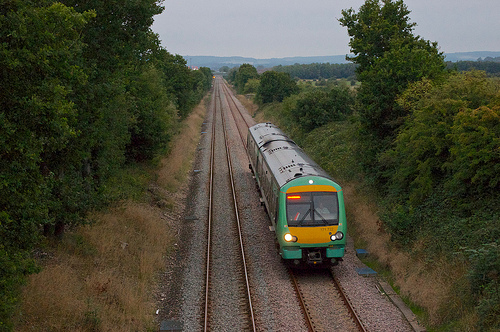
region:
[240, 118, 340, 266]
the train is in motion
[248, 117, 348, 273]
the train is green and yellow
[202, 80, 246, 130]
two rail road tracks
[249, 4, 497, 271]
the bushes are near a train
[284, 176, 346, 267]
the front of a train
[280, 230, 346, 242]
the headlights of a train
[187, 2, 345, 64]
the sky is foggy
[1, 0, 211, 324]
a stack of bushes and trees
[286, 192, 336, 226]
a person is maneuvering a train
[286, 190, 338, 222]
a train's windshield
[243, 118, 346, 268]
a short passenger train on the track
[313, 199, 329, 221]
the conductor of the train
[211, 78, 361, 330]
the train tracks on the ground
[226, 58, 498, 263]
the assorted trees on the side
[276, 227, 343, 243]
the headlights of the train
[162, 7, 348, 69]
a patch of blue sky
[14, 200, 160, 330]
some grass on the ground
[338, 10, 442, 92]
a tall green leafy tree near the train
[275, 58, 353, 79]
more green leafy trees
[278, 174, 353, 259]
the yellow and green front of the train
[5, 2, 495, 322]
a train going down the train track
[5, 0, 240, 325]
several trees beside a railroad track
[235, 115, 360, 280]
a passenger train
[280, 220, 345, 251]
the lights on the front of a train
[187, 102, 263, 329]
a rusty train track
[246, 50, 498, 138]
trees on a hillside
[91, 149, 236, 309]
grass along a train track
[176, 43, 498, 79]
a mountain range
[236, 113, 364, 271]
a yellow and green train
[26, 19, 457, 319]
railroad running through mountain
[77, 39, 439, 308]
train coming around mountain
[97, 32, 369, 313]
train tracks on hillside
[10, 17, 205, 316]
trees and grass lining tracks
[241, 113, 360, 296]
short train coming down tracks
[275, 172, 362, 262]
front of train is green and yellow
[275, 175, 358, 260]
window shows conductor seated at front of train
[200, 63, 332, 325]
railroad tracks with two lanes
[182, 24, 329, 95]
horizon line with mountains and sky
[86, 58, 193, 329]
green brush and yellow grass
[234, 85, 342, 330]
train on train tracks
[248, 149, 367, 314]
train's front is green and yellow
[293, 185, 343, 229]
a train driver in front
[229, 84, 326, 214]
train's roof is gray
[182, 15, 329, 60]
the sky is ovecast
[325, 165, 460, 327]
dry grass beside the train tracks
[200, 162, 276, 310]
pebbles on train tracks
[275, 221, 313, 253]
one light is on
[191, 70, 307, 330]
train track is long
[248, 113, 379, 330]
the train is short